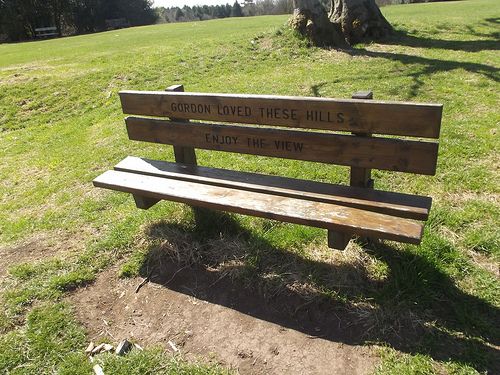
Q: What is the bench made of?
A: Wood.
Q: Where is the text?
A: On the bench.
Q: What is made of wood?
A: Bench.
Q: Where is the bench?
A: Park.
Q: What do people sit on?
A: Bench.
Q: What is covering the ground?
A: Grass.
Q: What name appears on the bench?
A: Gordon.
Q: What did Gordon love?
A: These hills.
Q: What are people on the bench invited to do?
A: Enjoy the view.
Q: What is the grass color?
A: Green.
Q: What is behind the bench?
A: Tree.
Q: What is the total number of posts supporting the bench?
A: 2.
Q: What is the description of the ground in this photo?
A: Patch or brown dirt.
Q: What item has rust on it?
A: Seat portion of park bench.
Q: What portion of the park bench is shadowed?
A: Back portion.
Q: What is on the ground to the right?
A: Shadow of tree.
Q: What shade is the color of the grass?
A: The grass is green.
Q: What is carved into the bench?
A: The bench has words carved.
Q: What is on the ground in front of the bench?
A: A shadow.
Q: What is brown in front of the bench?
A: The dirt.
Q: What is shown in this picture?
A: Bench.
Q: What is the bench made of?
A: Wood.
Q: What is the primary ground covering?
A: Grass.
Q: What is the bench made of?
A: Wood.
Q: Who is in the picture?
A: No one.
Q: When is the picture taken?
A: Daytime.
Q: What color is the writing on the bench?
A: Black.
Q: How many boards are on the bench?
A: 4.